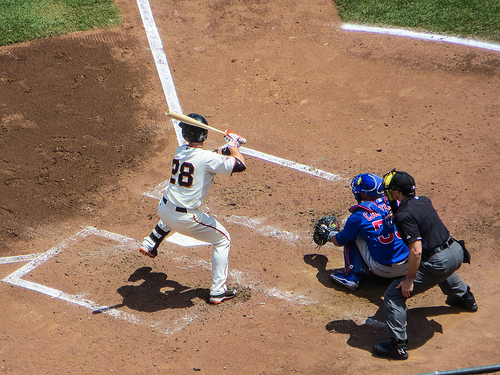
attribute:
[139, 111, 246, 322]
man — wearing white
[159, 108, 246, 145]
bat — wooden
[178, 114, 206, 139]
helmet — blue, black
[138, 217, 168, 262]
leg — lifted, raised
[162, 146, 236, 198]
jersey — white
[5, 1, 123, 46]
grass — green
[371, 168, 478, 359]
umpire — squatting, wearing black, wearing grey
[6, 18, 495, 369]
ground — sandy, wet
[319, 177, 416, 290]
catcher — blue, crouching, wearing blue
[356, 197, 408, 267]
jersey — blue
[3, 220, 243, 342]
chalk — white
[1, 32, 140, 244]
dirt — brown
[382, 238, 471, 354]
pants — grey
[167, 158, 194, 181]
number — black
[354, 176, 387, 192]
helmet — blue